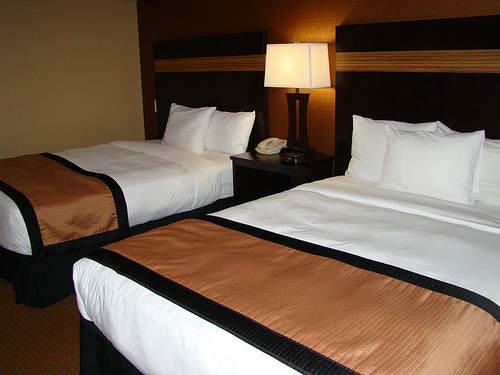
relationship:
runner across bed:
[103, 211, 495, 370] [3, 126, 234, 269]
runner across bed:
[2, 147, 123, 240] [62, 167, 497, 372]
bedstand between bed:
[224, 131, 334, 178] [9, 104, 254, 220]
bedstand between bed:
[224, 131, 334, 178] [107, 124, 490, 368]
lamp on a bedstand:
[230, 22, 350, 175] [224, 131, 334, 178]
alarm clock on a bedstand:
[283, 151, 309, 164] [224, 131, 334, 178]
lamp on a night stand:
[230, 22, 350, 175] [225, 138, 331, 198]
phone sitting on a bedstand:
[236, 119, 310, 185] [224, 131, 317, 178]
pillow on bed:
[353, 122, 434, 180] [72, 15, 499, 372]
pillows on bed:
[165, 100, 250, 155] [1, 115, 269, 295]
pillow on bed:
[353, 107, 434, 180] [72, 15, 499, 372]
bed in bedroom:
[72, 15, 499, 372] [1, 1, 497, 371]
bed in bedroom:
[9, 107, 232, 274] [1, 1, 497, 371]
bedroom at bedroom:
[1, 1, 497, 371] [1, 1, 497, 371]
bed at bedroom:
[9, 107, 232, 274] [1, 1, 497, 371]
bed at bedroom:
[72, 15, 499, 372] [1, 1, 497, 371]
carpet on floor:
[0, 280, 79, 373] [1, 280, 81, 373]